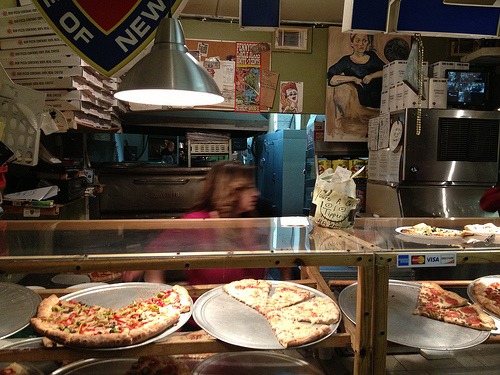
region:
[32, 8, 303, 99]
A sign is hanging from the ceiling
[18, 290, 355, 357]
Pizza is on a pan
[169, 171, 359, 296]
A woman is behind the counter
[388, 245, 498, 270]
Credit card logos are pictured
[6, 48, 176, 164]
Empty pizza boxes are on the shelf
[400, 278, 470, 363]
The pizza has pepperoni on it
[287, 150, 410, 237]
A paper bag is on the counter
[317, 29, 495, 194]
A painting is on the wall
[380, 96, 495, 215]
A stove is by the wall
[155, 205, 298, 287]
A woman is wearing a pink shirt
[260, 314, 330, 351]
Once slice of pizza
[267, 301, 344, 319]
Once slice of pizza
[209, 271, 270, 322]
Once slice of pizza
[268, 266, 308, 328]
Once slice of pizza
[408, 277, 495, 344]
Once slice of pizza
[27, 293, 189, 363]
Once slice of pizza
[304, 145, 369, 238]
Trash on the counter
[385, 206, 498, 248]
Trash on the counter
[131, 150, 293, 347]
Woman wearing a pink shirt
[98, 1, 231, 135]
Silver light hanging over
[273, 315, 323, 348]
slice of pizza on a pan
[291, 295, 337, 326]
slice of pizza on pan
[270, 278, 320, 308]
slice of pizza on pan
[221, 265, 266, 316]
pizza on a pan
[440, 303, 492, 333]
pizza on a pan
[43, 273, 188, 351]
pizza on a pan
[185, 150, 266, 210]
woman in a kitchen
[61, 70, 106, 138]
pizza boxes on a shelf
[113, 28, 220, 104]
light in a ceiling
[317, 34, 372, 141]
picture on a wall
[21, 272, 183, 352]
Pizza on a pie pan.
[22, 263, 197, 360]
Slice pizza on a pie pan.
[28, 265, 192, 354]
Small pizza on a pie pan.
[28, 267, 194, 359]
Pizza with toppings on a pie pan.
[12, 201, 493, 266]
Brown shelf in a restaurant.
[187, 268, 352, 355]
Grey pizza pan with pizza on it.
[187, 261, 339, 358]
Large grey pizza pan with pizza on it.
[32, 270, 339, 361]
Two grey pizza pan with pizza on it.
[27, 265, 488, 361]
Three grey pizza pan's with pizza on it.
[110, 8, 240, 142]
Light in a restaurant.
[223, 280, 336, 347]
half of a pizza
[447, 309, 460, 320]
pepperoni on the pizza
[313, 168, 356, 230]
decorated tip jar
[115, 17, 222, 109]
metal light that is on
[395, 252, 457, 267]
sticker that indicates credit cards accepted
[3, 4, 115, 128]
stack of empty pizza boxes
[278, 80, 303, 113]
drawing on the wall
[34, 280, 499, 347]
pizza display case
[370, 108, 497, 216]
large metal pizza oven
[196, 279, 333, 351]
round metal pizza tray